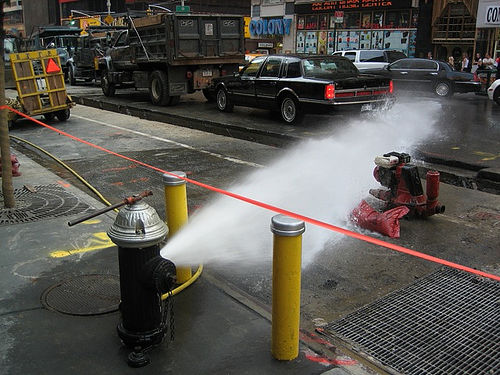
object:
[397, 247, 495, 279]
tape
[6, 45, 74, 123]
trailer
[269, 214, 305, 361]
pole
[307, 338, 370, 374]
curb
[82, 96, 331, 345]
lane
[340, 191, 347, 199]
water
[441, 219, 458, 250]
ground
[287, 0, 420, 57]
store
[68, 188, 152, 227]
wrench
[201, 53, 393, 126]
car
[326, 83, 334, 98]
taillight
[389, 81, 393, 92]
taillight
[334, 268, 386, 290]
ground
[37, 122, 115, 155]
orange tape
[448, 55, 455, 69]
person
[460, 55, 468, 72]
person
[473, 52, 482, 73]
person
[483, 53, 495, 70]
person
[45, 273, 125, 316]
black manhole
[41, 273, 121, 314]
cover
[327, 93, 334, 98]
light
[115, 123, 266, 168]
lane marking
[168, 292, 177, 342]
chain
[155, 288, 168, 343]
chains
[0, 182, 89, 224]
drainage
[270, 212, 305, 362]
sign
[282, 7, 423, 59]
building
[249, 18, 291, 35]
colony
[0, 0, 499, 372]
street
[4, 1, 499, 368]
city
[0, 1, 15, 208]
tree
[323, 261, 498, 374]
drain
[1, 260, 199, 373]
sidewalk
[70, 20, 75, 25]
light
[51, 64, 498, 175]
road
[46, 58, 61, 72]
caution sign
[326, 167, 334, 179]
water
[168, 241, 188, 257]
water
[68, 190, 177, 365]
fire hydrant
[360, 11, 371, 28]
window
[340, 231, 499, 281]
line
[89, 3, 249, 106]
dump truck